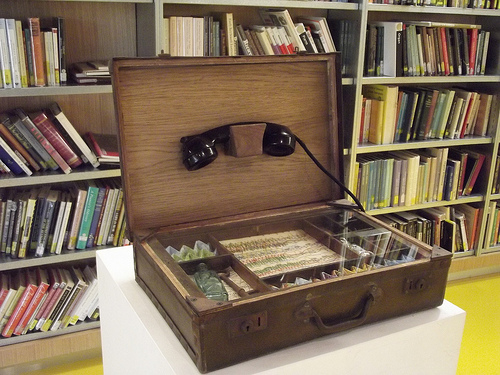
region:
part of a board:
[163, 192, 190, 224]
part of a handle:
[321, 303, 353, 340]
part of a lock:
[241, 310, 274, 337]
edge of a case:
[193, 293, 233, 335]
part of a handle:
[326, 313, 356, 333]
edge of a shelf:
[38, 261, 65, 279]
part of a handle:
[325, 314, 357, 349]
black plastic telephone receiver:
[166, 124, 306, 164]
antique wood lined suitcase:
[110, 56, 464, 368]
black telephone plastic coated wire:
[300, 138, 378, 223]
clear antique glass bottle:
[192, 256, 237, 304]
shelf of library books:
[0, 177, 130, 255]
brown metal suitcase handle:
[293, 283, 386, 333]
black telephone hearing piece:
[174, 120, 224, 175]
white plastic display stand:
[88, 272, 171, 374]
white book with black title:
[383, 18, 403, 76]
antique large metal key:
[213, 261, 258, 301]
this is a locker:
[168, 84, 380, 342]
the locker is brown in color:
[134, 80, 276, 141]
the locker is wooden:
[126, 86, 195, 118]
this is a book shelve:
[394, 18, 497, 201]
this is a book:
[52, 11, 69, 76]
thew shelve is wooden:
[388, 75, 448, 86]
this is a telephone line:
[178, 120, 319, 174]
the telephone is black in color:
[187, 126, 209, 162]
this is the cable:
[302, 135, 377, 217]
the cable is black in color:
[308, 154, 330, 181]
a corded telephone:
[166, 108, 371, 205]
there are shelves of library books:
[0, 1, 482, 342]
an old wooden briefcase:
[76, 36, 463, 351]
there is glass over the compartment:
[151, 199, 399, 296]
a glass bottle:
[187, 259, 229, 311]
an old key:
[215, 265, 255, 305]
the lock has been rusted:
[213, 313, 278, 338]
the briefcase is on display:
[84, 25, 463, 367]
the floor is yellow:
[2, 257, 496, 373]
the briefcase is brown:
[87, 44, 475, 374]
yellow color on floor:
[464, 283, 496, 329]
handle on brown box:
[299, 298, 376, 333]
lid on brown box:
[111, 43, 355, 206]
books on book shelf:
[376, 94, 458, 129]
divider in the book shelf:
[373, 73, 495, 90]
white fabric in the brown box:
[169, 239, 209, 262]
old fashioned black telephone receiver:
[175, 122, 320, 169]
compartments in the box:
[165, 225, 409, 290]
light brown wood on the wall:
[67, 11, 138, 40]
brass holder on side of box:
[422, 238, 454, 265]